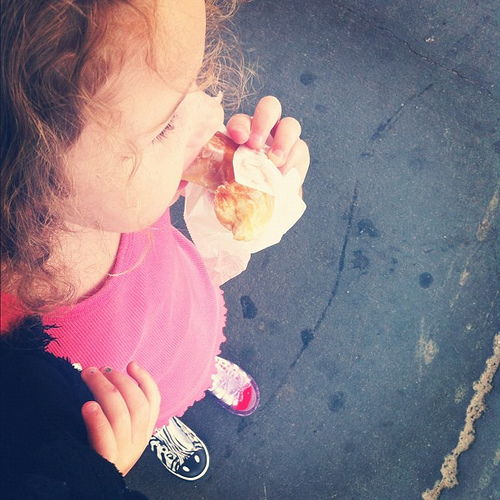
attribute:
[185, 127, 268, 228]
donut — being eaten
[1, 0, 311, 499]
girl — eating, fair skinned, young, standing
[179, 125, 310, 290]
wrapper — white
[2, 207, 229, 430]
shirt — pink, lavender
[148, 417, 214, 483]
shoe — black, white, zebra printed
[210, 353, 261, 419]
shoe — pink, white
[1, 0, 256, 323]
hair — curly, brown, dark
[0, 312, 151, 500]
stuffed toy — black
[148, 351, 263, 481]
shoes — mismatched